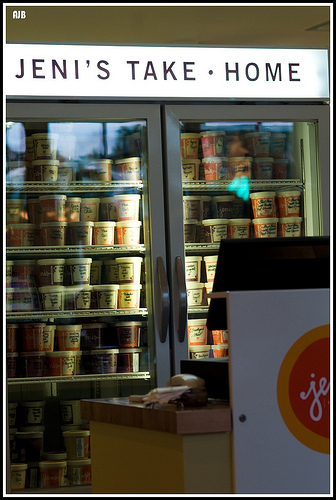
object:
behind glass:
[6, 120, 324, 496]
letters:
[300, 373, 329, 421]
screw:
[239, 414, 247, 423]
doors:
[2, 104, 171, 494]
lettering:
[79, 266, 87, 278]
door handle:
[175, 256, 187, 343]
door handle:
[156, 256, 169, 343]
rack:
[6, 180, 144, 191]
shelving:
[8, 372, 151, 386]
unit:
[6, 41, 324, 497]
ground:
[280, 103, 307, 124]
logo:
[277, 324, 330, 455]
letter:
[15, 59, 301, 82]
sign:
[6, 44, 329, 99]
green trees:
[123, 53, 200, 81]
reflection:
[162, 292, 186, 298]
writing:
[300, 373, 334, 421]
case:
[6, 131, 302, 493]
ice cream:
[113, 194, 140, 222]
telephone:
[166, 374, 205, 389]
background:
[0, 0, 335, 237]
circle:
[276, 324, 331, 456]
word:
[225, 62, 301, 81]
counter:
[81, 397, 232, 494]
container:
[7, 130, 302, 489]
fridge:
[4, 101, 330, 496]